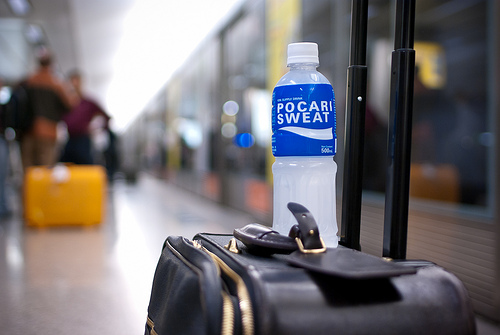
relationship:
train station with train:
[4, 2, 497, 335] [113, 1, 499, 279]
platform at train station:
[3, 153, 281, 334] [4, 2, 497, 335]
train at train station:
[113, 1, 499, 279] [4, 2, 497, 335]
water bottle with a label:
[273, 42, 343, 246] [271, 90, 332, 146]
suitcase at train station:
[24, 165, 101, 228] [4, 2, 497, 335]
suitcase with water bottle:
[149, 212, 476, 335] [273, 42, 343, 246]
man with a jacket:
[3, 56, 64, 167] [15, 76, 67, 134]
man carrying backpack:
[3, 56, 64, 167] [4, 82, 33, 132]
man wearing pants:
[3, 56, 64, 167] [26, 137, 53, 168]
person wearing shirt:
[61, 73, 105, 160] [72, 95, 108, 135]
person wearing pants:
[61, 73, 105, 160] [65, 130, 91, 165]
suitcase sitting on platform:
[24, 165, 101, 228] [3, 153, 281, 334]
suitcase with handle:
[149, 212, 476, 335] [243, 206, 323, 258]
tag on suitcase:
[285, 243, 419, 286] [149, 212, 476, 335]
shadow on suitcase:
[311, 264, 419, 317] [149, 212, 476, 335]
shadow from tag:
[311, 264, 419, 317] [285, 243, 419, 286]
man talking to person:
[3, 56, 64, 167] [61, 73, 105, 160]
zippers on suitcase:
[167, 229, 254, 332] [149, 212, 476, 335]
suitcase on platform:
[24, 165, 101, 228] [3, 153, 281, 334]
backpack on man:
[4, 82, 33, 132] [3, 56, 64, 167]